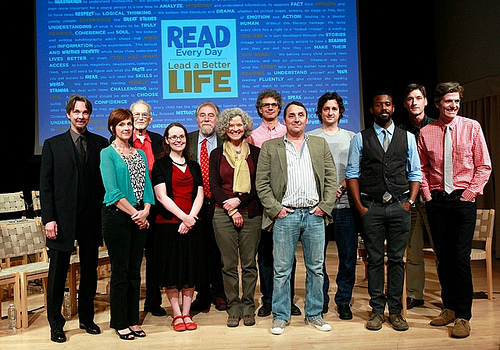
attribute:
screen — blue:
[32, 1, 366, 156]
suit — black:
[39, 130, 109, 326]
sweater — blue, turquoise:
[101, 143, 157, 208]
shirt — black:
[152, 154, 205, 218]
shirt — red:
[157, 160, 193, 223]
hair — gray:
[214, 106, 253, 139]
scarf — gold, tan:
[221, 138, 254, 197]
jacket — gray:
[254, 134, 339, 228]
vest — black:
[359, 126, 410, 201]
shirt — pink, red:
[416, 116, 493, 201]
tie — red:
[199, 138, 212, 200]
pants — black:
[46, 247, 99, 328]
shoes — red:
[171, 313, 199, 333]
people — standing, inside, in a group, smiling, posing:
[37, 78, 492, 343]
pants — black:
[424, 190, 476, 320]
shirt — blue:
[345, 123, 423, 186]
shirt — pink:
[248, 120, 288, 147]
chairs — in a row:
[1, 216, 120, 328]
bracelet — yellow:
[229, 207, 239, 217]